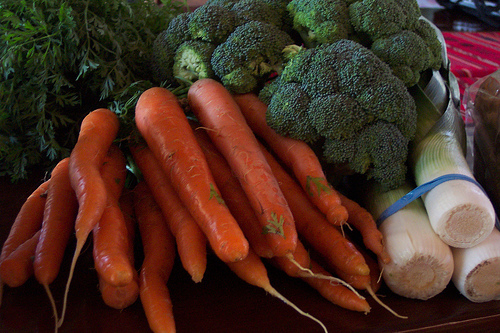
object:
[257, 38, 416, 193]
broccoli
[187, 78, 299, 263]
carrots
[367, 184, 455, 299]
leeks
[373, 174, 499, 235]
rubberband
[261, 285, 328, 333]
roots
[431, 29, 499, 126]
cloth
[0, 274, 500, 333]
table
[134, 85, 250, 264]
carrot